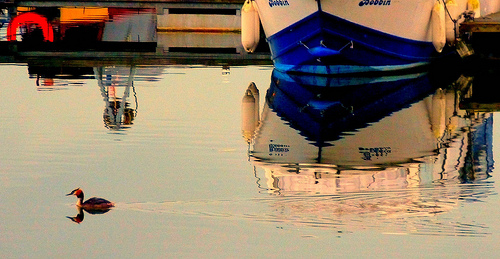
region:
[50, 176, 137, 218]
a bird is in the water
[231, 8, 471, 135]
a boat is in the water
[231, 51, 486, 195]
the boats reflection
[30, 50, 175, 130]
another reflection on the water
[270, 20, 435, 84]
the bottom portion of the boat is blue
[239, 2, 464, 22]
the top portion of the boat is white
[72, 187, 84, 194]
the birds head has red feathers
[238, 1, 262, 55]
a sand bags on the outside of the boat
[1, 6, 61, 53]
a life saver can be seen in the distance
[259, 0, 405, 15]
some wording is on the boat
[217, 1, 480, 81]
Boat on the water.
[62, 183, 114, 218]
Duck in the water.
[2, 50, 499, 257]
Water covering the surface.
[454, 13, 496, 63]
Pier beside the boat.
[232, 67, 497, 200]
Reflection of boat on the water.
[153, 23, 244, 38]
Stripe on the structure.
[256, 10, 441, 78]
blue bottom on the boat.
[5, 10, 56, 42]
Red ring in the background.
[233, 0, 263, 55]
White buoy on the boat.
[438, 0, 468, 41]
rope on the side of the boat.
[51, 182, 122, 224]
a reflection of a bird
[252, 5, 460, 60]
this is a boat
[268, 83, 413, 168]
this is a reflection of a boat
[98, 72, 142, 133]
that is a reflection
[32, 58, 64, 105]
that is a reflection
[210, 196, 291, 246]
the water is calm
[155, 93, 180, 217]
the water is calm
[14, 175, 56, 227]
the water is calm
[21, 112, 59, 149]
the water is calm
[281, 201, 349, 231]
the water is calm